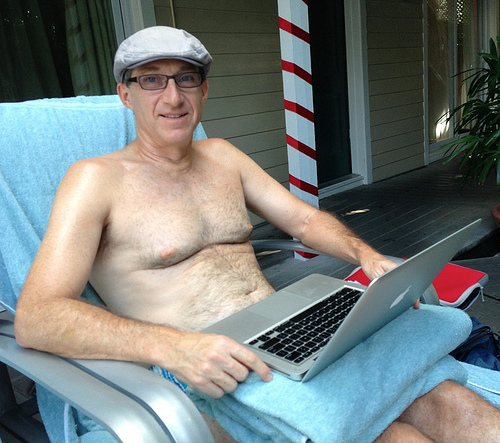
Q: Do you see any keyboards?
A: Yes, there is a keyboard.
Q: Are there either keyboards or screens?
A: Yes, there is a keyboard.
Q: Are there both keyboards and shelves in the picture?
A: No, there is a keyboard but no shelves.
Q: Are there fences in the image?
A: No, there are no fences.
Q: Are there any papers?
A: No, there are no papers.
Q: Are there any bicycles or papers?
A: No, there are no papers or bicycles.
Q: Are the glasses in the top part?
A: Yes, the glasses are in the top of the image.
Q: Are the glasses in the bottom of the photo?
A: No, the glasses are in the top of the image.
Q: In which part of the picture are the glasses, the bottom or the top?
A: The glasses are in the top of the image.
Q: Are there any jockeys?
A: No, there are no jockeys.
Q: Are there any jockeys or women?
A: No, there are no jockeys or women.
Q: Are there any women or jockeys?
A: No, there are no jockeys or women.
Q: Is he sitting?
A: Yes, the man is sitting.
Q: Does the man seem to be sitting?
A: Yes, the man is sitting.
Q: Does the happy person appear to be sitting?
A: Yes, the man is sitting.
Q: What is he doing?
A: The man is sitting.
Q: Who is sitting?
A: The man is sitting.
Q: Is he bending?
A: No, the man is sitting.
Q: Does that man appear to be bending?
A: No, the man is sitting.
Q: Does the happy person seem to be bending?
A: No, the man is sitting.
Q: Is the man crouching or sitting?
A: The man is sitting.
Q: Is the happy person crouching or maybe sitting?
A: The man is sitting.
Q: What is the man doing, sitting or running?
A: The man is sitting.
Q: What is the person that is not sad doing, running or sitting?
A: The man is sitting.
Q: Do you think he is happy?
A: Yes, the man is happy.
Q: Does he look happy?
A: Yes, the man is happy.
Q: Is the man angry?
A: No, the man is happy.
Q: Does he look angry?
A: No, the man is happy.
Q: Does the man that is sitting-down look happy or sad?
A: The man is happy.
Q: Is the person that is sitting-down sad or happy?
A: The man is happy.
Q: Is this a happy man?
A: Yes, this is a happy man.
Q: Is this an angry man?
A: No, this is a happy man.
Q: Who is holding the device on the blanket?
A: The man is holding the computer.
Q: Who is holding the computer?
A: The man is holding the computer.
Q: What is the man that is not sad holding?
A: The man is holding the computer.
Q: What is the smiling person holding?
A: The man is holding the computer.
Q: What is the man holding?
A: The man is holding the computer.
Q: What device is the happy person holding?
A: The man is holding the computer.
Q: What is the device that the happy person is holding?
A: The device is a computer.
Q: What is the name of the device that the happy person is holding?
A: The device is a computer.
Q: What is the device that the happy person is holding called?
A: The device is a computer.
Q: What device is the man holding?
A: The man is holding the computer.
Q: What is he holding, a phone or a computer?
A: The man is holding a computer.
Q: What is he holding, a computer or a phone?
A: The man is holding a computer.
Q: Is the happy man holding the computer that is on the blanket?
A: Yes, the man is holding the computer.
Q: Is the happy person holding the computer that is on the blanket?
A: Yes, the man is holding the computer.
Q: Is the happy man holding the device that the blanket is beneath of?
A: Yes, the man is holding the computer.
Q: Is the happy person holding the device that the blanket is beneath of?
A: Yes, the man is holding the computer.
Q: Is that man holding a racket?
A: No, the man is holding the computer.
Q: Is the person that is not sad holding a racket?
A: No, the man is holding the computer.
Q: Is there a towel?
A: Yes, there is a towel.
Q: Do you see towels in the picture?
A: Yes, there is a towel.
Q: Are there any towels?
A: Yes, there is a towel.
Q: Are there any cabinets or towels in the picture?
A: Yes, there is a towel.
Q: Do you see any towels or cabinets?
A: Yes, there is a towel.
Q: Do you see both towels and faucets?
A: No, there is a towel but no faucets.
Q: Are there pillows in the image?
A: No, there are no pillows.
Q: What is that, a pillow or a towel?
A: That is a towel.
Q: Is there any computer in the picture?
A: Yes, there is a computer.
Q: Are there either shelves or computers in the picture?
A: Yes, there is a computer.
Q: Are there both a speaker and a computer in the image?
A: No, there is a computer but no speakers.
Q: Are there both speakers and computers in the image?
A: No, there is a computer but no speakers.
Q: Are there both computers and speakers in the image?
A: No, there is a computer but no speakers.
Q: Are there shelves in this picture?
A: No, there are no shelves.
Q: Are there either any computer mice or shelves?
A: No, there are no shelves or computer mice.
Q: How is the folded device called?
A: The device is a computer.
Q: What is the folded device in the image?
A: The device is a computer.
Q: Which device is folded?
A: The device is a computer.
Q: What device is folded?
A: The device is a computer.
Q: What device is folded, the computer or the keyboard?
A: The computer is folded.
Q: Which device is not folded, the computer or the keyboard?
A: The keyboard is not folded.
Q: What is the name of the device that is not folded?
A: The device is a keyboard.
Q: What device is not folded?
A: The device is a keyboard.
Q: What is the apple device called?
A: The device is a computer.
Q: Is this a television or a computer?
A: This is a computer.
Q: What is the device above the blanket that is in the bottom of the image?
A: The device is a computer.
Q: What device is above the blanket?
A: The device is a computer.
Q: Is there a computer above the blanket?
A: Yes, there is a computer above the blanket.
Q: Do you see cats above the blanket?
A: No, there is a computer above the blanket.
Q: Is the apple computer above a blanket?
A: Yes, the computer is above a blanket.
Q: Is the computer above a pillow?
A: No, the computer is above a blanket.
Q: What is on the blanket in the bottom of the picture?
A: The computer is on the blanket.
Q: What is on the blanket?
A: The computer is on the blanket.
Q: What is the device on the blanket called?
A: The device is a computer.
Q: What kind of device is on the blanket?
A: The device is a computer.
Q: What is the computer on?
A: The computer is on the blanket.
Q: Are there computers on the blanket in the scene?
A: Yes, there is a computer on the blanket.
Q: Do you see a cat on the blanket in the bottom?
A: No, there is a computer on the blanket.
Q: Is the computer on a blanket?
A: Yes, the computer is on a blanket.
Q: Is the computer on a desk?
A: No, the computer is on a blanket.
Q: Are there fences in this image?
A: No, there are no fences.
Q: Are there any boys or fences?
A: No, there are no fences or boys.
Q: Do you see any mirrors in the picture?
A: No, there are no mirrors.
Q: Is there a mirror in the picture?
A: No, there are no mirrors.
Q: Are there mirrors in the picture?
A: No, there are no mirrors.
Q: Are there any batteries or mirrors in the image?
A: No, there are no mirrors or batteries.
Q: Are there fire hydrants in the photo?
A: No, there are no fire hydrants.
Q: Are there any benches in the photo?
A: No, there are no benches.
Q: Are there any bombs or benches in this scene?
A: No, there are no benches or bombs.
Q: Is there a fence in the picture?
A: No, there are no fences.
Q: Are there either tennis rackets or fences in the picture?
A: No, there are no fences or tennis rackets.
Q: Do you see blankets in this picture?
A: Yes, there is a blanket.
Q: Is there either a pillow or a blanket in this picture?
A: Yes, there is a blanket.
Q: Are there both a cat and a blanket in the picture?
A: No, there is a blanket but no cats.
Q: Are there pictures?
A: No, there are no pictures.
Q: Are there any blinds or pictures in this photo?
A: No, there are no pictures or blinds.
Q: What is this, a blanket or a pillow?
A: This is a blanket.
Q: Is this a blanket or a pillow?
A: This is a blanket.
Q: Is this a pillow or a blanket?
A: This is a blanket.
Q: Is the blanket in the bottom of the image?
A: Yes, the blanket is in the bottom of the image.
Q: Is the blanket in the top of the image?
A: No, the blanket is in the bottom of the image.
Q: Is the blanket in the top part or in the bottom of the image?
A: The blanket is in the bottom of the image.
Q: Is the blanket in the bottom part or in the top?
A: The blanket is in the bottom of the image.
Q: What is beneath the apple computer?
A: The blanket is beneath the computer.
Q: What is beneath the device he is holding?
A: The blanket is beneath the computer.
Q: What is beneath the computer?
A: The blanket is beneath the computer.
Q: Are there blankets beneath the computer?
A: Yes, there is a blanket beneath the computer.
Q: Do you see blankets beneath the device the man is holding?
A: Yes, there is a blanket beneath the computer.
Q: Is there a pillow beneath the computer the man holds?
A: No, there is a blanket beneath the computer.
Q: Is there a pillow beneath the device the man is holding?
A: No, there is a blanket beneath the computer.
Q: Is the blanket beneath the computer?
A: Yes, the blanket is beneath the computer.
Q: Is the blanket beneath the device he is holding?
A: Yes, the blanket is beneath the computer.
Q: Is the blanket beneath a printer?
A: No, the blanket is beneath the computer.